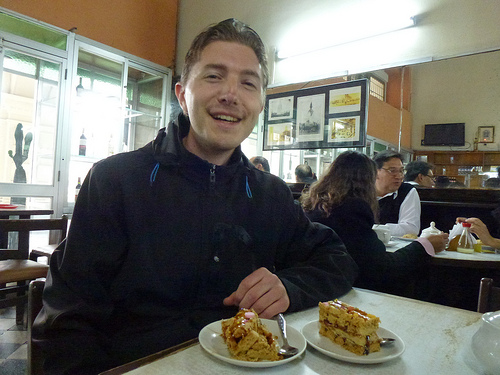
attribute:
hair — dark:
[371, 145, 407, 175]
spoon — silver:
[274, 312, 298, 358]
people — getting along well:
[35, 18, 419, 373]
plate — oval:
[298, 303, 408, 365]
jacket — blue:
[33, 108, 360, 373]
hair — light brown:
[179, 18, 269, 88]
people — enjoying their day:
[24, 13, 434, 360]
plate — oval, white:
[195, 313, 305, 367]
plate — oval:
[388, 348, 408, 368]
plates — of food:
[213, 340, 362, 370]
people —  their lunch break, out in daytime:
[42, 17, 354, 374]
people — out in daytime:
[302, 147, 432, 299]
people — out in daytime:
[366, 149, 424, 239]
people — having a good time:
[104, 16, 444, 273]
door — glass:
[12, 14, 159, 235]